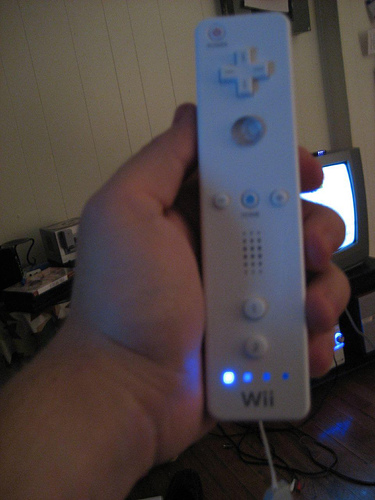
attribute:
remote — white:
[195, 11, 310, 421]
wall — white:
[1, 5, 329, 263]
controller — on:
[167, 14, 340, 476]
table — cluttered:
[6, 243, 72, 313]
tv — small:
[305, 166, 369, 276]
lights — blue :
[216, 367, 293, 387]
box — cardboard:
[40, 220, 94, 268]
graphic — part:
[239, 391, 277, 411]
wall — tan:
[15, 20, 154, 147]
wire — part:
[259, 432, 285, 469]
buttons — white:
[175, 180, 301, 230]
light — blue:
[218, 368, 237, 388]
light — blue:
[263, 371, 271, 380]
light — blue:
[281, 372, 288, 380]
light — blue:
[332, 331, 344, 349]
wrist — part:
[53, 269, 216, 473]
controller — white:
[186, 7, 321, 435]